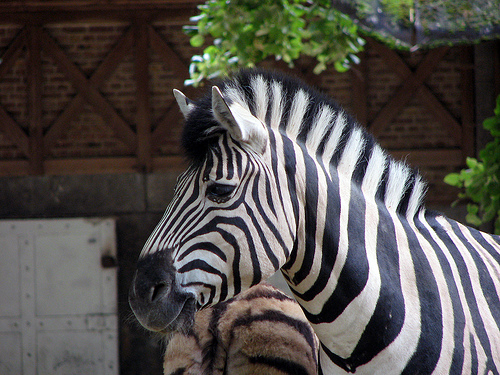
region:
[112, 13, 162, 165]
brown wood beams on the wall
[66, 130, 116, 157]
brown brick surface of the wall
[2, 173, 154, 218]
grey concrete lentil of the door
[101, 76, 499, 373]
two zebras standing outside of a building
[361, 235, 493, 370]
black and white stripes of the zebra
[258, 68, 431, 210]
black and white mane of the zebra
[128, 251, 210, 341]
black nose and mouth of the zebra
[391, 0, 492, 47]
green moss growing on the roof of the building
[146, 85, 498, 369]
the zebra is black and white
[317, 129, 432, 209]
the mane is black and white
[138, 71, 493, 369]
the zebra is in a zoo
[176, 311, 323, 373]
the zebra is brown and black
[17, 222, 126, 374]
the door is mettalic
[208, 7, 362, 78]
trees leaves are in the air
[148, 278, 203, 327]
the mouth is black in color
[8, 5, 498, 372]
the photo was taken during the day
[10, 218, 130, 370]
the door is white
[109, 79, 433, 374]
the zebra has stripes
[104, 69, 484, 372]
the zebra has stripes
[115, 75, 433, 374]
the zebra has stripes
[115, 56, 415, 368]
the zebra has stripes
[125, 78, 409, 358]
the zebra has stripes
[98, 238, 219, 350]
zebra's nose is black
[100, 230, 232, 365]
zebra's nose is black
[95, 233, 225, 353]
zebra's nose is black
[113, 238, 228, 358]
zebra's nose is black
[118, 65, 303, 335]
head of a zebra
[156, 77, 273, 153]
ear of a zebra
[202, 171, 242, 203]
eye of a zebra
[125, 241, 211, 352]
mouth of a zebra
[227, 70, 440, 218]
hair of a zebra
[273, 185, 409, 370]
neck of a zebra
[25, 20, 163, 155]
a brick wall behind zebra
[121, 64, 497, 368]
one big zebra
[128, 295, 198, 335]
mouth of a zebra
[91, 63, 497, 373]
black and white zebra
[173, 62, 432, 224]
hair running along the neck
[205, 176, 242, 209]
black eye on the side of the head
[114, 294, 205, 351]
thin hairs sticking off the snout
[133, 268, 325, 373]
a zebra's behind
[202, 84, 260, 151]
ear sticking out of the top of the head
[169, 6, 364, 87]
light green leaves on the branc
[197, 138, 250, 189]
four black stripes above the eye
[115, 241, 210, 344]
black snout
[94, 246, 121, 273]
black mark on the wall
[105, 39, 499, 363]
a black and white zebra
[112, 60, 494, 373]
the zebra is stripes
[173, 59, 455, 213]
mane on the zebra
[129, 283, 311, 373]
back of a zebra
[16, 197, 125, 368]
door in the background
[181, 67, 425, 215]
The mohawk of the zebra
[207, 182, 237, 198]
The eye of the zebra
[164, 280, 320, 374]
The rear of the zebra